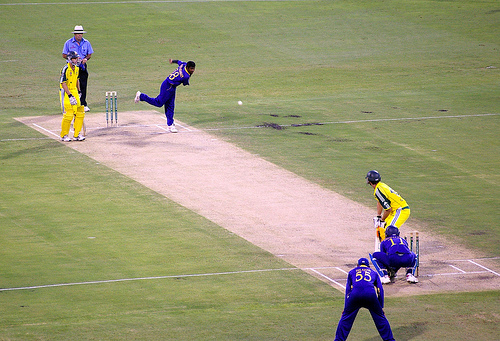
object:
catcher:
[369, 225, 422, 286]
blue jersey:
[379, 236, 411, 258]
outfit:
[370, 182, 412, 237]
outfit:
[58, 62, 89, 138]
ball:
[237, 100, 243, 105]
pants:
[57, 90, 89, 138]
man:
[331, 257, 393, 341]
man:
[133, 58, 196, 132]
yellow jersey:
[372, 183, 409, 210]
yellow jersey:
[57, 63, 84, 91]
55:
[354, 268, 376, 283]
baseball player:
[365, 168, 410, 237]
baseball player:
[58, 50, 90, 143]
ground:
[12, 60, 499, 314]